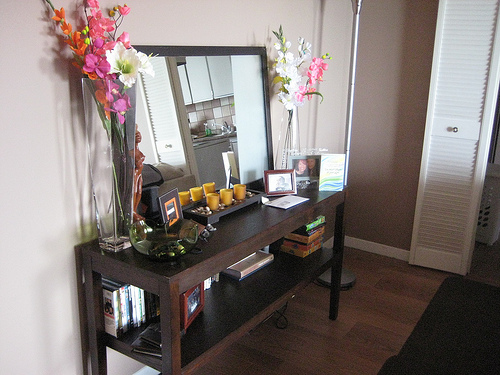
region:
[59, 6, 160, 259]
flowers in glass vase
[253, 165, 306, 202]
wood frame on picture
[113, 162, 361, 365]
wood table with shelf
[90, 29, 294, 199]
mirror resting against wall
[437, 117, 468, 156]
knob on closet door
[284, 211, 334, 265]
stack of books on shelf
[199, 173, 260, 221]
row of yellow candles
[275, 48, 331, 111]
white and pink flowers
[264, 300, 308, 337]
electrical wire under shelf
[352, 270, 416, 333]
floor made of wood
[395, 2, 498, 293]
the long white door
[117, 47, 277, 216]
the large framed mirror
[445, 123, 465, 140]
the knob on the white door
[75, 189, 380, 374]
the brown wooden table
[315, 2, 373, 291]
the silver metal lamp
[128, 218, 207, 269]
the green decorative dish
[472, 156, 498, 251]
the white laundry hamper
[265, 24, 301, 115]
the beautiful white gladiolas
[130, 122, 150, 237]
the brown sculpted statue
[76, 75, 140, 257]
the long rectangular vase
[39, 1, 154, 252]
a crystal vase with flowers in it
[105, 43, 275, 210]
a framed mirror against the wall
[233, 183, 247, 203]
yellow candle holders on the table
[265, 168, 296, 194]
a picture and frame on the table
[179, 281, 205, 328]
a wooden picture frame on the bottom shelf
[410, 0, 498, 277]
an white slat closet door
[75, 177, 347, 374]
a wooden foyer table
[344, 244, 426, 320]
a wooden panel floor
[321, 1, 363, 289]
a metal floor lamp pole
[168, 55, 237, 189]
a reflection in the mirror of the kitchen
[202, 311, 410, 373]
The floor is wooden.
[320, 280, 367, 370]
The floor is wooden.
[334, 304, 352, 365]
The floor is wooden.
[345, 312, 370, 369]
The floor is wooden.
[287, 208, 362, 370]
The floor is wooden.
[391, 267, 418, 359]
The floor is wooden.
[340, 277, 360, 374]
The floor is wooden.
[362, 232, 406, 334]
The floor is wooden.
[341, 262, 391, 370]
The floor is wooden.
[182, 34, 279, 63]
wood frame on mirror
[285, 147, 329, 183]
picture of people in frame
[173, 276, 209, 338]
picture on table shelf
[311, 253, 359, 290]
stand of floor lamp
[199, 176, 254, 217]
three yellow candles in a row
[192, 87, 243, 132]
reflection of kitchen tile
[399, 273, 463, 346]
rug on wood floor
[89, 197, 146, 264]
glass vase on table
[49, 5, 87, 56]
orange flowers in front of wall